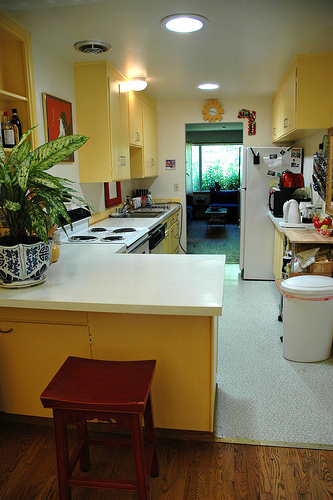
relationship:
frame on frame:
[42, 91, 76, 164] [37, 88, 82, 168]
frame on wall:
[42, 91, 76, 164] [32, 44, 84, 213]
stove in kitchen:
[69, 213, 149, 245] [39, 49, 294, 302]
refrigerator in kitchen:
[235, 142, 303, 282] [1, 0, 332, 497]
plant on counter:
[0, 125, 96, 246] [2, 237, 224, 315]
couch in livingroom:
[207, 189, 237, 220] [188, 137, 239, 254]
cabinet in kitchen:
[253, 68, 331, 153] [1, 0, 332, 497]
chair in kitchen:
[38, 351, 164, 496] [15, 24, 332, 340]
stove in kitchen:
[61, 203, 181, 255] [1, 0, 332, 497]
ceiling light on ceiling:
[165, 16, 204, 34] [3, 1, 332, 94]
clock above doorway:
[175, 97, 246, 131] [183, 120, 242, 264]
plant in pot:
[0, 125, 90, 241] [0, 228, 52, 290]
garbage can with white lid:
[280, 274, 333, 363] [280, 274, 331, 292]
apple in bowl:
[312, 216, 318, 221] [315, 227, 331, 235]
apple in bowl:
[312, 216, 331, 229] [315, 227, 331, 235]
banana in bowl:
[317, 224, 330, 231] [315, 227, 331, 235]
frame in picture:
[39, 86, 59, 97] [56, 105, 71, 135]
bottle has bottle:
[3, 111, 19, 147] [1, 111, 19, 148]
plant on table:
[0, 125, 96, 246] [0, 245, 229, 319]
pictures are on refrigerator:
[263, 146, 303, 176] [235, 142, 303, 282]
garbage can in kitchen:
[280, 269, 331, 363] [1, 0, 332, 497]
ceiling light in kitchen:
[128, 79, 148, 91] [1, 0, 332, 497]